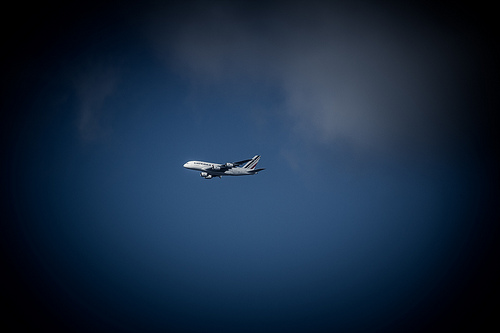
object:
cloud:
[0, 0, 500, 333]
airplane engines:
[224, 162, 233, 169]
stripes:
[245, 155, 260, 169]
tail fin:
[246, 167, 266, 172]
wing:
[243, 154, 261, 170]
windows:
[208, 165, 211, 167]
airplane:
[182, 154, 267, 179]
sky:
[0, 0, 500, 333]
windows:
[193, 162, 195, 164]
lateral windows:
[200, 163, 203, 166]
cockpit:
[182, 160, 196, 169]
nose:
[183, 161, 191, 169]